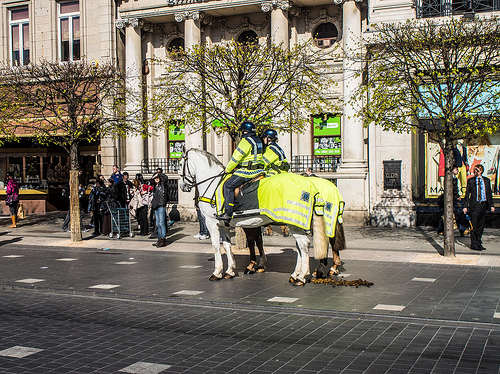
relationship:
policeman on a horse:
[224, 118, 262, 219] [179, 143, 332, 286]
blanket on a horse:
[216, 172, 325, 232] [179, 143, 332, 286]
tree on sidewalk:
[349, 3, 500, 256] [1, 212, 500, 266]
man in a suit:
[463, 162, 494, 250] [463, 176, 495, 248]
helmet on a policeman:
[238, 120, 258, 134] [224, 118, 262, 219]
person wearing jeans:
[139, 172, 174, 247] [153, 209, 170, 245]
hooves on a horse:
[209, 268, 310, 286] [179, 143, 332, 286]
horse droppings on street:
[299, 273, 378, 292] [3, 248, 499, 373]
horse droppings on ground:
[299, 273, 378, 292] [3, 248, 499, 373]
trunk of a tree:
[444, 144, 456, 259] [349, 3, 500, 256]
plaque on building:
[382, 157, 404, 194] [367, 1, 499, 233]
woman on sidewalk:
[2, 169, 24, 228] [1, 212, 500, 266]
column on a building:
[116, 18, 151, 174] [116, 3, 369, 224]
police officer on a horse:
[258, 128, 285, 172] [179, 143, 332, 286]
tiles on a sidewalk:
[1, 243, 499, 309] [1, 212, 500, 266]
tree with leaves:
[349, 3, 500, 256] [360, 13, 497, 144]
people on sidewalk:
[86, 166, 171, 248] [1, 212, 500, 266]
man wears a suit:
[463, 162, 494, 250] [463, 176, 495, 248]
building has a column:
[116, 3, 369, 224] [116, 18, 151, 174]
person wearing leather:
[139, 172, 174, 247] [151, 169, 168, 208]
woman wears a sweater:
[2, 169, 24, 228] [7, 173, 19, 203]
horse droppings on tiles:
[299, 273, 378, 292] [1, 243, 499, 309]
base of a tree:
[69, 169, 82, 235] [1, 63, 164, 242]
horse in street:
[179, 143, 332, 286] [3, 248, 499, 373]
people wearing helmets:
[86, 166, 171, 248] [240, 119, 283, 141]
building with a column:
[116, 3, 369, 224] [116, 18, 151, 174]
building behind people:
[116, 3, 369, 224] [86, 166, 171, 248]